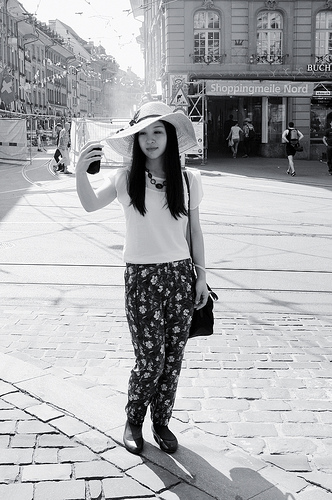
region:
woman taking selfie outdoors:
[64, 85, 232, 472]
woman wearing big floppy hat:
[89, 89, 208, 168]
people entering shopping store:
[218, 113, 259, 156]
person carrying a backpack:
[275, 117, 309, 178]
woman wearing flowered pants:
[96, 254, 203, 429]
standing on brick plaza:
[16, 287, 315, 494]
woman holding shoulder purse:
[178, 163, 221, 338]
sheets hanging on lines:
[66, 110, 204, 178]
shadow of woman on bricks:
[127, 432, 312, 499]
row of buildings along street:
[8, 3, 129, 139]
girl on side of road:
[79, 99, 217, 391]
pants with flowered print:
[111, 256, 201, 423]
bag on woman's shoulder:
[182, 167, 220, 342]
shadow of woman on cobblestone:
[139, 440, 233, 498]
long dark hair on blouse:
[161, 162, 188, 221]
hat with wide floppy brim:
[106, 93, 205, 156]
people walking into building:
[221, 110, 262, 158]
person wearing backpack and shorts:
[275, 121, 308, 177]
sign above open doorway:
[202, 78, 312, 98]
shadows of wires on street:
[47, 201, 72, 257]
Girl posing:
[65, 93, 259, 299]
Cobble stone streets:
[57, 354, 119, 473]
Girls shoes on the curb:
[92, 420, 234, 487]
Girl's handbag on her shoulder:
[171, 179, 241, 375]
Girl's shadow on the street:
[133, 420, 242, 498]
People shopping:
[210, 78, 324, 224]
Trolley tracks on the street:
[16, 150, 65, 194]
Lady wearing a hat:
[100, 57, 214, 207]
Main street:
[57, 18, 197, 177]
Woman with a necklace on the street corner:
[33, 21, 195, 198]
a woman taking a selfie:
[21, 55, 299, 350]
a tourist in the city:
[84, 38, 320, 490]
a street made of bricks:
[228, 351, 318, 450]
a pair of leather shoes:
[112, 419, 186, 460]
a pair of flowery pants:
[114, 256, 198, 429]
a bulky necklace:
[140, 165, 179, 190]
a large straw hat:
[99, 95, 209, 161]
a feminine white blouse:
[105, 160, 212, 261]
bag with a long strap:
[180, 164, 226, 344]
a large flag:
[0, 63, 22, 108]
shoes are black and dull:
[113, 405, 194, 462]